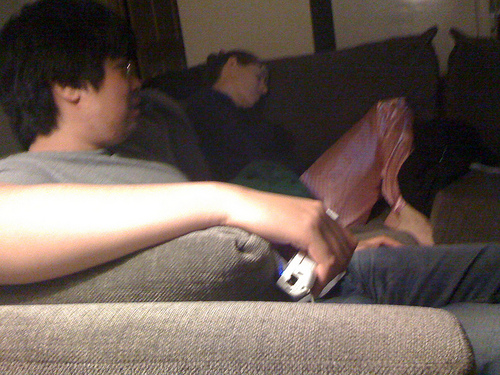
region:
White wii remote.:
[273, 207, 338, 299]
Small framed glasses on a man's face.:
[102, 60, 135, 78]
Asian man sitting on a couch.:
[1, 2, 498, 374]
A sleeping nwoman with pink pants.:
[178, 47, 434, 245]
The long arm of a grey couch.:
[1, 302, 475, 374]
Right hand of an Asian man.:
[245, 185, 358, 295]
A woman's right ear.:
[224, 52, 238, 77]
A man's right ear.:
[51, 67, 81, 104]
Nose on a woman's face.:
[260, 75, 268, 96]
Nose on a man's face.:
[128, 67, 142, 94]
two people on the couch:
[6, 3, 493, 370]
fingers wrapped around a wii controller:
[252, 191, 367, 315]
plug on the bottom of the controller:
[276, 270, 301, 290]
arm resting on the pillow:
[0, 167, 364, 299]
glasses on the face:
[101, 57, 150, 84]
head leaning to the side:
[203, 40, 278, 115]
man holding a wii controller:
[2, 2, 499, 372]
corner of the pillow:
[226, 228, 269, 265]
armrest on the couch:
[1, 299, 493, 374]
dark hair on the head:
[3, 5, 140, 145]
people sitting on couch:
[7, 53, 438, 290]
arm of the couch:
[10, 324, 460, 368]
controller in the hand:
[237, 190, 347, 306]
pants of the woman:
[282, 65, 424, 217]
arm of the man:
[31, 186, 308, 255]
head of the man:
[63, 10, 145, 153]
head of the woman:
[152, 33, 289, 108]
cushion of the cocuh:
[117, 228, 266, 303]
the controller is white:
[280, 267, 342, 306]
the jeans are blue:
[370, 238, 480, 300]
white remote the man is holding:
[277, 197, 339, 287]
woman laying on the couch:
[193, 33, 443, 242]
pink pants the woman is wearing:
[310, 82, 412, 219]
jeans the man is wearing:
[335, 229, 498, 354]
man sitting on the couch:
[0, 2, 499, 359]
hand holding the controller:
[238, 189, 355, 294]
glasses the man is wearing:
[108, 52, 137, 79]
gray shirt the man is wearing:
[2, 145, 290, 275]